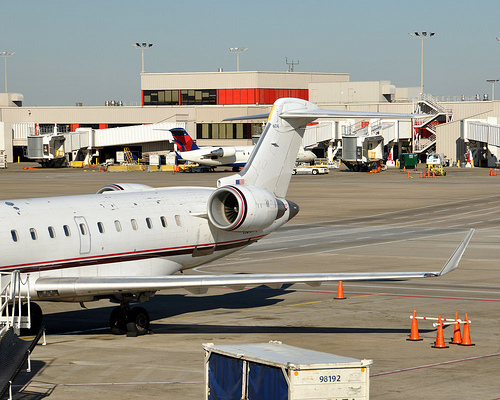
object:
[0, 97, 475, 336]
plane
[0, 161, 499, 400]
tarmac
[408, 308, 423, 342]
cone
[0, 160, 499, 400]
ground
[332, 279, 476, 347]
cones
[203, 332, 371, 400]
luggage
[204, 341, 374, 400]
cart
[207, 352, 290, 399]
curtain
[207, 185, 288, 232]
engine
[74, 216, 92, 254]
door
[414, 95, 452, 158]
stairs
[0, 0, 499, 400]
background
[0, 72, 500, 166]
building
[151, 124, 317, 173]
planes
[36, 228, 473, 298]
wing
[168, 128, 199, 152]
tail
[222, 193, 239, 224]
turbine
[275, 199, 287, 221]
tip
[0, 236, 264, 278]
line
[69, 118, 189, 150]
walkway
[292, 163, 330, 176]
vehicle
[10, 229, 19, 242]
windows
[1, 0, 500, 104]
sky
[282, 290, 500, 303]
lines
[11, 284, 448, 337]
shadow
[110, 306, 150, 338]
wheels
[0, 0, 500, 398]
airport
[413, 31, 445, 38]
lights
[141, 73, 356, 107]
terminal